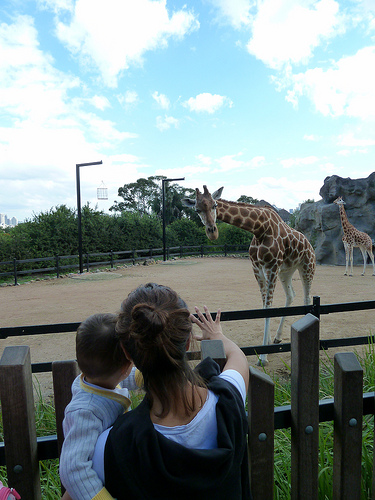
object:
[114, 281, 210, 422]
hair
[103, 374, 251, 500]
sweater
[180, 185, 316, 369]
giraffe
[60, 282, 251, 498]
woman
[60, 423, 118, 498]
arm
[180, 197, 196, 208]
ear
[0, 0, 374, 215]
sky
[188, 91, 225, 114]
cloud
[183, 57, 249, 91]
blue sky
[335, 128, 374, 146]
white cloud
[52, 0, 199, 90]
cloud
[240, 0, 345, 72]
cloud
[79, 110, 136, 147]
cloud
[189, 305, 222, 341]
hand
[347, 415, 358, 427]
bolts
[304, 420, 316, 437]
bolts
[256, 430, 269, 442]
bolts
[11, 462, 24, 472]
bolts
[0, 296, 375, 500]
fence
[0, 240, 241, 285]
fence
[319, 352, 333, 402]
grass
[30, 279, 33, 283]
rock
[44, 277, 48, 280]
rock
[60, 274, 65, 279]
rock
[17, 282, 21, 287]
rock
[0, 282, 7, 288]
rock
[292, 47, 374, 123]
cloud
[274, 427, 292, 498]
grass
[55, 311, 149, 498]
baby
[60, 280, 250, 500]
lady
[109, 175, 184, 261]
tree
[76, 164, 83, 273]
pole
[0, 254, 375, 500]
ground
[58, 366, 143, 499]
sweater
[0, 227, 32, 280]
trees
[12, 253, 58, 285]
section